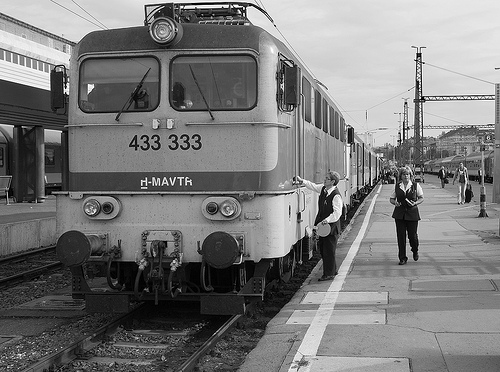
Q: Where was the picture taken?
A: In a train station.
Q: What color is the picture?
A: Black and white.